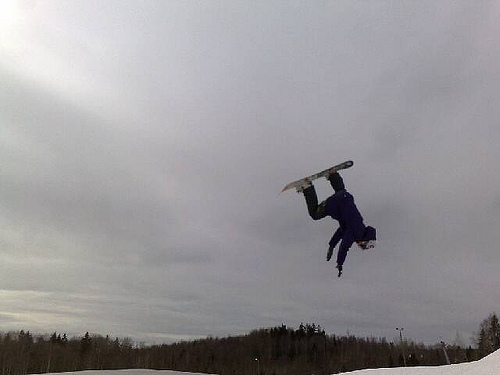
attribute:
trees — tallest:
[2, 314, 498, 371]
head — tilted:
[357, 223, 380, 255]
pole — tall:
[387, 321, 417, 366]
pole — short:
[432, 326, 461, 373]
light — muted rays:
[3, 2, 155, 135]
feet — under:
[295, 170, 337, 192]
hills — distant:
[33, 296, 424, 364]